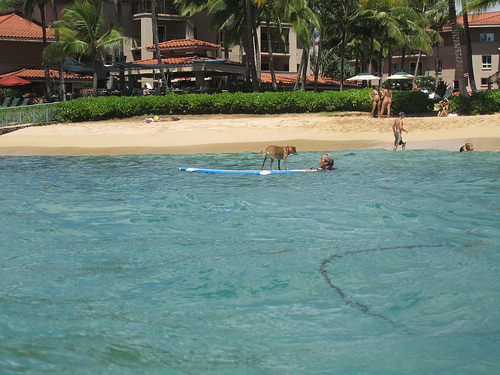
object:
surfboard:
[176, 165, 321, 173]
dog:
[258, 142, 295, 167]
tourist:
[358, 82, 463, 150]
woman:
[435, 94, 455, 121]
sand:
[420, 117, 484, 145]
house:
[415, 9, 498, 88]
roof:
[429, 0, 495, 30]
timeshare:
[0, 0, 496, 98]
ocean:
[4, 149, 498, 374]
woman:
[369, 85, 382, 112]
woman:
[379, 84, 394, 114]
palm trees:
[109, 2, 347, 102]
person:
[393, 110, 409, 149]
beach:
[82, 94, 486, 149]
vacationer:
[305, 153, 336, 172]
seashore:
[340, 147, 498, 161]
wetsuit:
[440, 104, 447, 113]